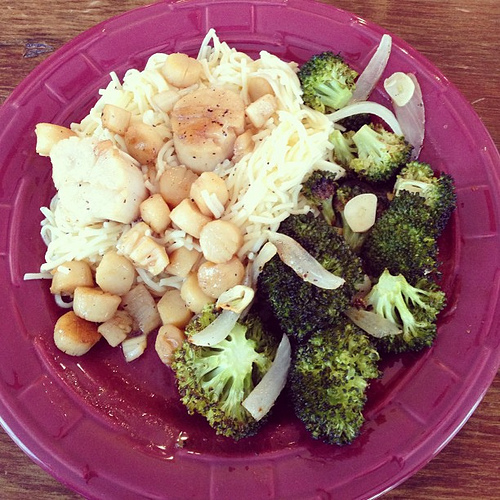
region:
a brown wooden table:
[1, 0, 499, 498]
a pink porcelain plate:
[0, 0, 499, 498]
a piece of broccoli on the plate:
[170, 307, 286, 443]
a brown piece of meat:
[195, 217, 245, 264]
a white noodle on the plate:
[193, 22, 219, 61]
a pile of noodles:
[16, 18, 345, 322]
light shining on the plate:
[396, 40, 413, 58]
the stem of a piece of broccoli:
[353, 118, 385, 151]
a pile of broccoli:
[155, 45, 455, 458]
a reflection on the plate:
[3, 366, 38, 394]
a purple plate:
[118, 449, 181, 489]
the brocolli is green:
[299, 339, 372, 414]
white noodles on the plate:
[237, 165, 298, 211]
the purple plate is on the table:
[419, 419, 497, 474]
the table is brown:
[452, 435, 494, 480]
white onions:
[239, 366, 284, 423]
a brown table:
[426, 34, 499, 84]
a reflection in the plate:
[116, 377, 161, 427]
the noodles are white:
[255, 159, 304, 206]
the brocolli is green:
[303, 361, 353, 398]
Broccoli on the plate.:
[176, 135, 454, 400]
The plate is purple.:
[71, 395, 222, 498]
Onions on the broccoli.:
[256, 217, 343, 309]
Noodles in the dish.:
[227, 120, 336, 222]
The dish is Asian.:
[20, 40, 453, 423]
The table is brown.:
[2, 4, 88, 69]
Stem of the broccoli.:
[364, 266, 423, 318]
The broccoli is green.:
[302, 337, 362, 431]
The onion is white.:
[230, 344, 305, 416]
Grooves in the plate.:
[19, 362, 111, 469]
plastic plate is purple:
[27, 18, 457, 393]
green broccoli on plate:
[221, 131, 446, 428]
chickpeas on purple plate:
[62, 56, 246, 378]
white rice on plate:
[79, 29, 336, 319]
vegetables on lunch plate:
[129, 203, 440, 488]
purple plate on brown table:
[19, 49, 472, 471]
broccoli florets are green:
[152, 316, 302, 393]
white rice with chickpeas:
[39, 94, 348, 309]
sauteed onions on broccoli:
[214, 65, 362, 485]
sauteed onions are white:
[209, 51, 405, 415]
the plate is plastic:
[120, 456, 234, 492]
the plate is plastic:
[150, 388, 282, 496]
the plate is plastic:
[130, 386, 225, 488]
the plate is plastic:
[159, 439, 224, 488]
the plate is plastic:
[50, 449, 172, 494]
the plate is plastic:
[79, 383, 156, 458]